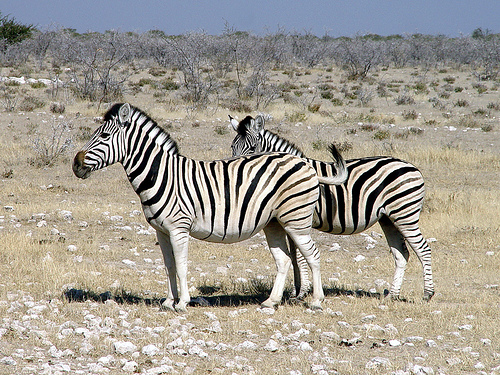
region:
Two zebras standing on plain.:
[62, 83, 470, 328]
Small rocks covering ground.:
[35, 313, 479, 373]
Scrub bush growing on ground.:
[309, 70, 491, 137]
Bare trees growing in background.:
[56, 22, 381, 107]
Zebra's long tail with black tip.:
[318, 140, 358, 195]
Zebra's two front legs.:
[150, 232, 213, 318]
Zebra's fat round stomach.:
[193, 199, 279, 246]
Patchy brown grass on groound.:
[422, 131, 498, 283]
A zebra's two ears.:
[220, 106, 273, 140]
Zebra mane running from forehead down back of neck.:
[102, 94, 188, 162]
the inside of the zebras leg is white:
[265, 237, 291, 312]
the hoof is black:
[305, 299, 325, 311]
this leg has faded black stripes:
[169, 229, 196, 314]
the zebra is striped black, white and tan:
[70, 96, 354, 323]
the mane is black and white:
[96, 97, 182, 154]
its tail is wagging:
[282, 136, 368, 205]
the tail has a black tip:
[325, 139, 347, 171]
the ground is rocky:
[10, 304, 499, 374]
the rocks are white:
[3, 76, 60, 86]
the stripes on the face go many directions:
[95, 114, 125, 167]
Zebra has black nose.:
[66, 143, 107, 209]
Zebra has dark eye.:
[97, 122, 129, 153]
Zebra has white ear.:
[118, 105, 139, 124]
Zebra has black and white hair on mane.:
[97, 97, 188, 155]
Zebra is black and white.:
[163, 140, 303, 235]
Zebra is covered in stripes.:
[159, 174, 249, 244]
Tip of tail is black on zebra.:
[323, 139, 366, 199]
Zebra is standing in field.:
[118, 273, 375, 348]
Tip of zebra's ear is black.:
[221, 104, 240, 129]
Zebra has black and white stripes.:
[332, 130, 407, 231]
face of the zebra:
[50, 84, 136, 186]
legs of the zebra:
[144, 237, 352, 307]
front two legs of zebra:
[152, 241, 224, 334]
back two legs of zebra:
[381, 250, 459, 320]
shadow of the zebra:
[43, 252, 203, 342]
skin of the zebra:
[180, 177, 267, 222]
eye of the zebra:
[93, 121, 115, 141]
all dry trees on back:
[34, 52, 486, 172]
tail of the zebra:
[321, 151, 356, 183]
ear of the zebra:
[108, 100, 141, 120]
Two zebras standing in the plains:
[85, 105, 447, 305]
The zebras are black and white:
[85, 105, 436, 288]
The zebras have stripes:
[75, 102, 424, 294]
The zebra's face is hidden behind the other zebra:
[222, 110, 274, 175]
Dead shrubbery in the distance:
[21, 21, 486, 80]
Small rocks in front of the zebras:
[35, 294, 412, 374]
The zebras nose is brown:
[69, 150, 96, 178]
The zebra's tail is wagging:
[312, 142, 357, 194]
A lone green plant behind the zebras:
[0, 14, 32, 46]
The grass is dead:
[422, 187, 492, 224]